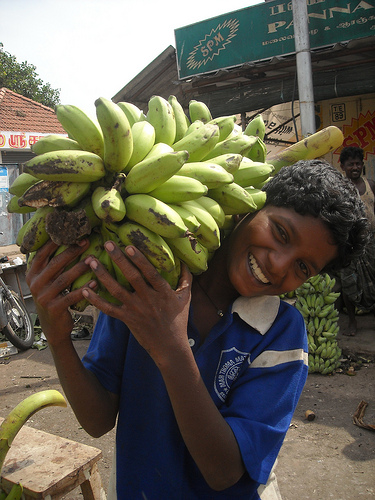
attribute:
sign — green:
[173, 3, 371, 81]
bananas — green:
[294, 272, 341, 374]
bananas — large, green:
[12, 87, 258, 308]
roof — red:
[1, 83, 70, 134]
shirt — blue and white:
[88, 301, 291, 488]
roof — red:
[13, 94, 62, 133]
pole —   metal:
[265, 5, 350, 167]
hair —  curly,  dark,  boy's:
[265, 155, 373, 277]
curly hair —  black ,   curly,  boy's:
[257, 160, 374, 270]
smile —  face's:
[243, 244, 277, 289]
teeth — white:
[246, 259, 272, 286]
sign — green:
[169, 12, 291, 59]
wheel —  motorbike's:
[1, 291, 34, 348]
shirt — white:
[74, 294, 308, 498]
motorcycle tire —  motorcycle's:
[1, 291, 39, 354]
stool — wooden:
[1, 418, 182, 493]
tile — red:
[6, 93, 17, 106]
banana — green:
[94, 96, 133, 171]